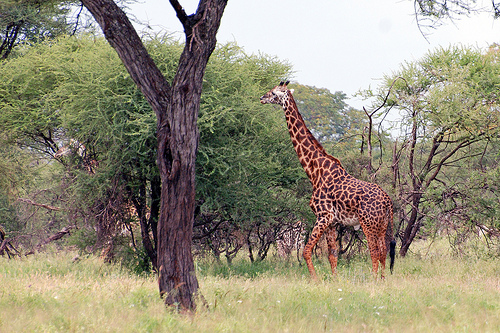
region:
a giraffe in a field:
[205, 37, 433, 323]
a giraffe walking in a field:
[240, 39, 466, 329]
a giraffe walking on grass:
[188, 32, 422, 330]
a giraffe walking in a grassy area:
[247, 48, 440, 308]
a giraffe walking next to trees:
[202, 49, 402, 329]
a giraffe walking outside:
[236, 22, 477, 331]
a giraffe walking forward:
[245, 64, 427, 299]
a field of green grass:
[220, 295, 370, 312]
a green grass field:
[230, 290, 439, 330]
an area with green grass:
[207, 260, 309, 331]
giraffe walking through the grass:
[249, 78, 409, 279]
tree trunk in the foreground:
[85, 1, 232, 316]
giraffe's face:
[247, 81, 304, 114]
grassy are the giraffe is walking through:
[2, 246, 499, 327]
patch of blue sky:
[126, 0, 498, 97]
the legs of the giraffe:
[293, 213, 395, 278]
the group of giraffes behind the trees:
[71, 142, 332, 277]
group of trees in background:
[5, 37, 498, 252]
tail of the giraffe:
[383, 200, 396, 236]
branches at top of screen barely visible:
[414, 3, 499, 42]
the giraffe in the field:
[242, 68, 430, 288]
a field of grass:
[0, 255, 490, 330]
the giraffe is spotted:
[259, 82, 416, 279]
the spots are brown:
[254, 68, 429, 278]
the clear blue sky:
[293, 9, 385, 69]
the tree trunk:
[146, 72, 211, 296]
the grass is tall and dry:
[246, 272, 438, 330]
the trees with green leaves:
[395, 75, 497, 171]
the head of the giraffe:
[243, 66, 305, 118]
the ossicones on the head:
[276, 72, 298, 89]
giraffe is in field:
[237, 86, 409, 273]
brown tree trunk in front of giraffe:
[130, 16, 217, 310]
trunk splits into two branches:
[107, 24, 252, 299]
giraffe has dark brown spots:
[288, 113, 489, 282]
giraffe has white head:
[270, 78, 288, 105]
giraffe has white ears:
[276, 81, 298, 97]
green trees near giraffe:
[124, 84, 286, 220]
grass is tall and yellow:
[180, 277, 355, 332]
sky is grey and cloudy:
[232, 9, 415, 74]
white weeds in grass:
[270, 270, 402, 328]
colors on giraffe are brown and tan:
[288, 110, 381, 257]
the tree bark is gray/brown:
[168, 89, 195, 301]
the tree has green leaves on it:
[40, 46, 135, 144]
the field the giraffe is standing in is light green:
[239, 280, 466, 322]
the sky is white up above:
[248, 9, 416, 64]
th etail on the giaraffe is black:
[386, 237, 401, 265]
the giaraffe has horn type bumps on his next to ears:
[270, 75, 286, 100]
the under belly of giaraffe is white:
[341, 212, 358, 222]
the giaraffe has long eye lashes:
[265, 88, 284, 102]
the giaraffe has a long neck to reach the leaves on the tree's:
[258, 82, 333, 159]